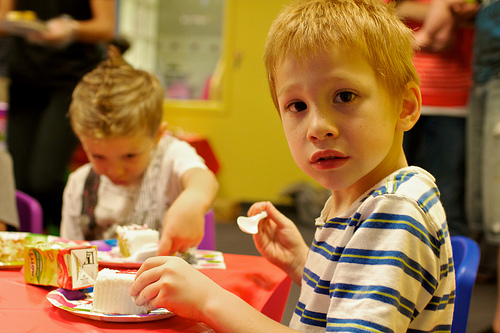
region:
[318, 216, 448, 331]
blue, yellow, and white striped shirt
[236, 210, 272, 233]
white plastic spoon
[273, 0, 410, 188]
young boy looking at the camera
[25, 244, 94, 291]
juice box laying on its side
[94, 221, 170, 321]
birthday cake with white frosting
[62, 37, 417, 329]
two children sitting at the table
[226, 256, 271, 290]
red plastic tablecloth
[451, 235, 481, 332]
back of a blue chair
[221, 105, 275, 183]
yellow wall in the background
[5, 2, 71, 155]
adult holding a plate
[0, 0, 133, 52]
Women holding a plate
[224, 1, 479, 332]
Boy wearing a white and blue striped shirt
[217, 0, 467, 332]
Boy holding a spoon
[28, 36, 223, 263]
Boy with plate full of cake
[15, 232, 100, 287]
Overturned juice box.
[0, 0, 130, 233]
Woman in black clothes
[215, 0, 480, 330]
Boy sitting in a blue chair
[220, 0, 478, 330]
Blonde haired boy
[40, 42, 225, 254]
Boy wearing a white shirt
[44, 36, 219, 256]
Boy sitting in a purple chair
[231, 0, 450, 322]
Child is looking at the camera.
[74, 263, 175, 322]
Little boy is eating cake.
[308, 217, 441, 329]
He is wearing a striped shirt.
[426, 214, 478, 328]
The chair is blue.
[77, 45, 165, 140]
Boy has a Mohawk.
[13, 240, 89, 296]
Juice box fell over.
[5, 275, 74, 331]
The table is red.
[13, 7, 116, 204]
Adult in background with cake.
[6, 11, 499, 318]
Picture was taken in a class room.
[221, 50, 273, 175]
Wall is yellow.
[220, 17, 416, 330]
a blonde boy looking at the camera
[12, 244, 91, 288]
a juice box sitting on its side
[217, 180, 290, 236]
a plastic spoon in a boy's hand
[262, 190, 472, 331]
a white and blue striped shirt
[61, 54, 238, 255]
a small boy with a faux hawk hairstyle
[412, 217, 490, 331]
a blue chair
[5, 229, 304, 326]
an orange table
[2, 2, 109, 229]
a blurry figure in black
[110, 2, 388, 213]
a yellow wall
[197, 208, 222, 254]
the corner of a purple chair with a boy in it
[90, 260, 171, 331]
piece of cake with frosting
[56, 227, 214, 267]
piece of cake on plate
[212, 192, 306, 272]
little boy holding plastic spoon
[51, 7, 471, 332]
little boy eating piece of cake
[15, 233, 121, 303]
apple juice box on table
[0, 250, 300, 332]
red kids table cloth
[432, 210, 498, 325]
blue plastic chair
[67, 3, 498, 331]
two boys sitting at table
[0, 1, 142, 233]
lady in black holding a plate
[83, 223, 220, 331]
little boy holding piece of cake